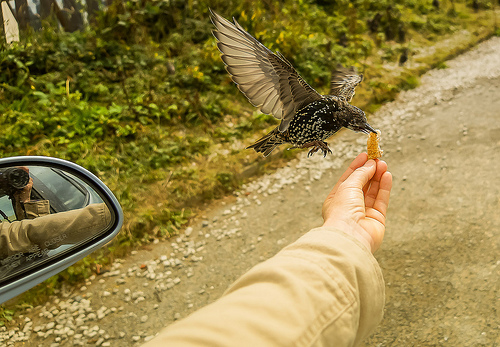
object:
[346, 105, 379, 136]
head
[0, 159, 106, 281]
window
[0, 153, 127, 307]
sideview mirror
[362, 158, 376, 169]
thumb nail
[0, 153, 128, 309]
mirror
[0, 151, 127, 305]
mans reflection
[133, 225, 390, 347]
jacket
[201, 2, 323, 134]
wing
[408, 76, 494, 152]
ground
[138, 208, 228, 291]
pebbles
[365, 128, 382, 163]
bread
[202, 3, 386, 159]
bird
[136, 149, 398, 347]
human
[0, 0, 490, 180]
greenery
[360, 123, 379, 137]
beak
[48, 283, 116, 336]
pebbles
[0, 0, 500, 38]
background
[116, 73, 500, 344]
road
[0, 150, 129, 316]
car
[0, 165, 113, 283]
man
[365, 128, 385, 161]
treat